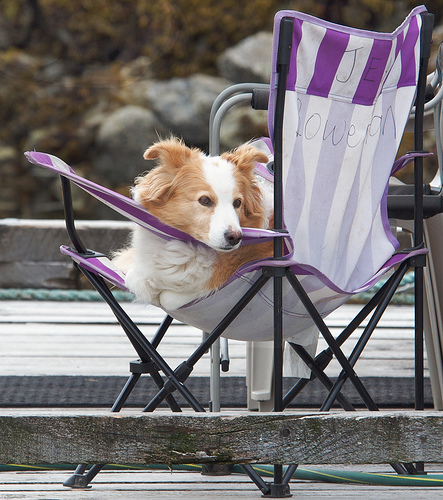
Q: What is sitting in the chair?
A: A dog.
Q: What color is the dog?
A: Brown and white.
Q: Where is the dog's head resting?
A: On the arm of the chair.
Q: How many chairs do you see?
A: 1.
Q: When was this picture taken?
A: Daytime.